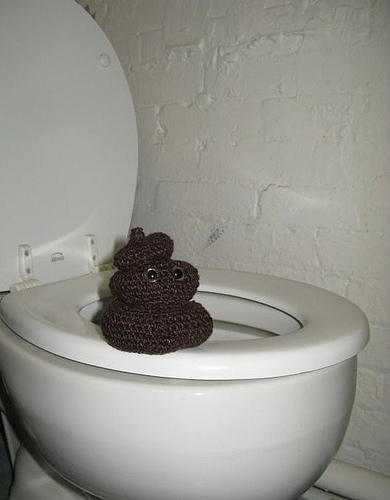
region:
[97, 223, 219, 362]
Small poop shaped fabric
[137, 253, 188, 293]
Two small black eyes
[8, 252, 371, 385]
White toilet bowl rim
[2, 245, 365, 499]
White toilet in bathroom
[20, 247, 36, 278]
two silver bolts on toilet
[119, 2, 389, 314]
White cracks on wall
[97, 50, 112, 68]
One white bolt on toilet lid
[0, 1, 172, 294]
White toilet lid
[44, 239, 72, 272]
Silver logo on toilet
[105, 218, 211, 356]
Brown piece of poop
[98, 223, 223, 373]
Brown piece of fabric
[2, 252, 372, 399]
White toilet lid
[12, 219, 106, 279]
Four silver bolts on toilet lid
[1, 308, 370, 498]
White toilet bowl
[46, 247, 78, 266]
Silver logo on toilet lid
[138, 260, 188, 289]
Two black eyes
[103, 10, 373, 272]
White cracks in the wall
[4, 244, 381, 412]
White toilet bowl lid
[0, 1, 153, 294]
White toilet bowl cover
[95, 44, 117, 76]
One white bolt on toilet bowl cover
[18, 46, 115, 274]
the cover of a toilet seat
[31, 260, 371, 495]
that is a toilet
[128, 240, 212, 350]
that is a doll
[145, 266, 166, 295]
the eye of a doll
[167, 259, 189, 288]
the eye of a doll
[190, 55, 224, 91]
wall of the toilet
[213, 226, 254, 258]
wall of the toilet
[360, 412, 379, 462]
wall of the toilet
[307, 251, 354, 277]
wall of the toilet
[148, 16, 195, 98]
wall of the toilet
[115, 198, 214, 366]
A black urgly frog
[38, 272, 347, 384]
A white toilet seat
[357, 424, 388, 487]
A white toilet wall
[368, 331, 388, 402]
A white toilet wall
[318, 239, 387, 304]
A white toilet wall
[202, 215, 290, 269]
A white toilet wall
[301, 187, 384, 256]
A white toilet wall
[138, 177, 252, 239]
A white toilet wall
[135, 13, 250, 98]
A white toilet wall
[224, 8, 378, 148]
A white toilet wall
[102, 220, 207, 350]
fake poop on toilet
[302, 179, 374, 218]
brick on the wall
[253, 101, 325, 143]
brick on the wall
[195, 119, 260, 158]
brick on the wall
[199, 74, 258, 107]
brick on the wall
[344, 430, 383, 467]
brick on the wall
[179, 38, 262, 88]
brick on the wall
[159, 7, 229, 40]
brick on the wall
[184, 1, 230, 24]
brick on the wall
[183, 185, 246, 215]
brick on the wall